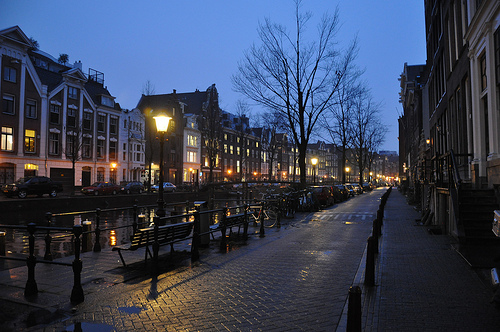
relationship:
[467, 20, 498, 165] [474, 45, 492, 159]
frame of window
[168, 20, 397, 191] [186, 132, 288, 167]
buildings with windows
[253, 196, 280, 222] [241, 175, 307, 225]
cycle in parking area